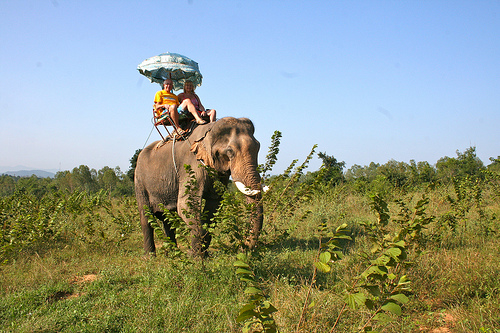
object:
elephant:
[134, 116, 270, 263]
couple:
[156, 78, 217, 136]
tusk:
[234, 181, 260, 196]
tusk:
[262, 183, 269, 193]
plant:
[353, 274, 416, 333]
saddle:
[152, 107, 197, 138]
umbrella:
[136, 53, 203, 90]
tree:
[436, 153, 464, 183]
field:
[6, 175, 499, 331]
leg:
[178, 182, 205, 261]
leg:
[133, 191, 158, 256]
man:
[155, 81, 182, 135]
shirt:
[155, 90, 179, 107]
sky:
[0, 0, 495, 180]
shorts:
[163, 106, 184, 117]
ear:
[191, 128, 216, 169]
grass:
[3, 265, 249, 331]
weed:
[235, 251, 275, 329]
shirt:
[181, 94, 200, 109]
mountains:
[0, 164, 69, 182]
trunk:
[228, 156, 263, 250]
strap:
[172, 131, 178, 173]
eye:
[229, 147, 234, 155]